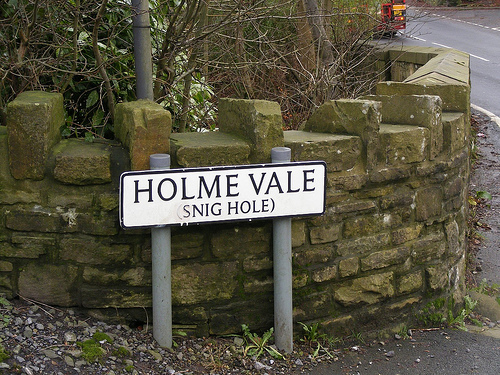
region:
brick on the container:
[336, 213, 387, 234]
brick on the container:
[318, 275, 387, 302]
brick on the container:
[173, 261, 234, 299]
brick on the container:
[407, 192, 447, 222]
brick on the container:
[367, 138, 425, 183]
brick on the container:
[67, 273, 138, 318]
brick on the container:
[26, 227, 63, 257]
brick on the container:
[61, 161, 98, 183]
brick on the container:
[339, 100, 382, 135]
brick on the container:
[419, 298, 464, 323]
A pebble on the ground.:
[33, 319, 45, 331]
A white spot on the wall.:
[381, 208, 394, 226]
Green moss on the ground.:
[80, 328, 110, 361]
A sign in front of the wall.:
[117, 145, 325, 357]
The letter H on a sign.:
[130, 177, 155, 205]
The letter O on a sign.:
[156, 176, 180, 201]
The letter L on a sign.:
[178, 174, 196, 200]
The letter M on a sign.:
[196, 173, 226, 200]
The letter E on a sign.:
[224, 170, 242, 199]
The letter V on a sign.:
[246, 170, 267, 197]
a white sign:
[117, 166, 326, 220]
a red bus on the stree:
[359, 2, 409, 34]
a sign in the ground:
[119, 137, 309, 348]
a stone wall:
[32, 153, 462, 320]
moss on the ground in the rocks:
[76, 338, 151, 370]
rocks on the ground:
[19, 318, 145, 358]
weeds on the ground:
[240, 323, 287, 359]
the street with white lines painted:
[448, 32, 497, 94]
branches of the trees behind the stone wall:
[6, 18, 364, 92]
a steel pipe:
[130, 18, 154, 101]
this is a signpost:
[130, 160, 324, 222]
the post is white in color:
[282, 194, 317, 211]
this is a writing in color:
[138, 173, 270, 208]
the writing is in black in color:
[132, 176, 266, 196]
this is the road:
[449, 13, 499, 32]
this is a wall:
[356, 122, 431, 300]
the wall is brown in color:
[354, 151, 439, 257]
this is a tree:
[17, 8, 120, 75]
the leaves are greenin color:
[81, 73, 93, 118]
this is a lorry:
[384, 5, 409, 30]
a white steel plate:
[115, 153, 332, 234]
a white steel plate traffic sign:
[102, 152, 337, 238]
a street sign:
[108, 154, 343, 234]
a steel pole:
[127, 135, 184, 356]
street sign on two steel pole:
[126, 142, 336, 354]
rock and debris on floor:
[21, 297, 229, 374]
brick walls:
[312, 43, 482, 318]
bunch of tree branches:
[181, 6, 383, 94]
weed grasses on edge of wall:
[400, 289, 494, 337]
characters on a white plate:
[104, 159, 337, 227]